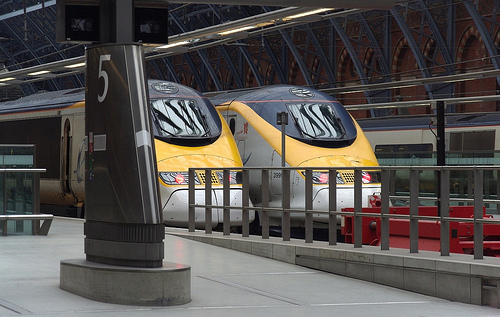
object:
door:
[56, 115, 72, 199]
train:
[0, 72, 259, 231]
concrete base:
[58, 261, 190, 308]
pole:
[85, 2, 167, 268]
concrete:
[3, 212, 498, 317]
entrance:
[56, 114, 72, 202]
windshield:
[287, 101, 349, 138]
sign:
[96, 52, 112, 102]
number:
[95, 52, 111, 102]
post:
[82, 43, 165, 270]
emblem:
[150, 79, 180, 94]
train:
[203, 84, 386, 240]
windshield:
[153, 98, 220, 135]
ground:
[195, 257, 499, 314]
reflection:
[285, 103, 347, 138]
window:
[287, 104, 348, 141]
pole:
[0, 166, 8, 236]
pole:
[14, 169, 23, 233]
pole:
[31, 173, 40, 234]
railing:
[342, 203, 493, 253]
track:
[231, 214, 494, 273]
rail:
[200, 85, 387, 232]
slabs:
[0, 291, 469, 317]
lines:
[201, 275, 296, 305]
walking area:
[0, 214, 490, 316]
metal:
[190, 159, 496, 269]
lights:
[54, 0, 172, 48]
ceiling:
[1, 0, 484, 90]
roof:
[183, 25, 493, 82]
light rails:
[145, 73, 430, 250]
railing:
[185, 164, 499, 265]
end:
[250, 93, 390, 226]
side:
[0, 89, 159, 200]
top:
[2, 77, 210, 112]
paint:
[152, 135, 241, 185]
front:
[145, 78, 259, 225]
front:
[241, 82, 382, 215]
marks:
[151, 291, 185, 305]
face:
[246, 81, 394, 219]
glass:
[0, 166, 37, 235]